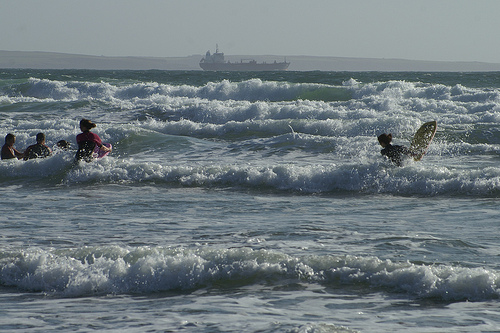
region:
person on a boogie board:
[347, 102, 447, 191]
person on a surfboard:
[352, 112, 460, 199]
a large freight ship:
[168, 34, 308, 101]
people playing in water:
[6, 114, 127, 174]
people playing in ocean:
[4, 111, 128, 171]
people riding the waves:
[6, 72, 151, 226]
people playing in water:
[4, 106, 497, 181]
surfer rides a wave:
[345, 110, 479, 195]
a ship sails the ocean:
[161, 32, 324, 92]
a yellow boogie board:
[399, 115, 452, 171]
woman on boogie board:
[338, 121, 456, 203]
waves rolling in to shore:
[82, 73, 389, 210]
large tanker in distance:
[180, 38, 315, 129]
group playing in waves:
[6, 116, 143, 207]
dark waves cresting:
[135, 77, 286, 179]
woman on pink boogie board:
[41, 97, 121, 178]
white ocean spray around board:
[329, 111, 455, 211]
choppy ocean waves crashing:
[76, 71, 347, 258]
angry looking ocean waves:
[122, 59, 417, 272]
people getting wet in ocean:
[17, 102, 435, 206]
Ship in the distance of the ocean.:
[197, 42, 289, 74]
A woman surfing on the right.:
[372, 121, 439, 166]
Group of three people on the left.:
[1, 115, 111, 168]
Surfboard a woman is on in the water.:
[407, 118, 436, 163]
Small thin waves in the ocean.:
[4, 241, 499, 303]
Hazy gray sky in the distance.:
[0, 0, 496, 64]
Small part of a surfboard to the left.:
[93, 143, 113, 165]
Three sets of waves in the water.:
[143, 76, 341, 141]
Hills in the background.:
[0, 47, 499, 72]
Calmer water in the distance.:
[0, 65, 499, 80]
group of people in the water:
[2, 116, 149, 177]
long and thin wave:
[13, 230, 497, 315]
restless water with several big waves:
[6, 76, 498, 312]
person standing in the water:
[71, 116, 114, 163]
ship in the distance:
[195, 44, 300, 79]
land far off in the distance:
[1, 43, 494, 72]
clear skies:
[1, 1, 498, 58]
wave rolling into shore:
[4, 232, 496, 315]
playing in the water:
[362, 121, 456, 174]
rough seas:
[2, 67, 497, 319]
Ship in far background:
[189, 39, 293, 79]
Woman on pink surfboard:
[71, 114, 114, 163]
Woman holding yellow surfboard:
[368, 114, 442, 180]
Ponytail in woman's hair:
[73, 116, 100, 137]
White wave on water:
[193, 80, 336, 218]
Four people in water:
[1, 114, 116, 176]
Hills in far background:
[316, 51, 468, 79]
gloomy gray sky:
[283, 13, 414, 46]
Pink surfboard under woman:
[86, 143, 111, 168]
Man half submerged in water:
[0, 124, 25, 169]